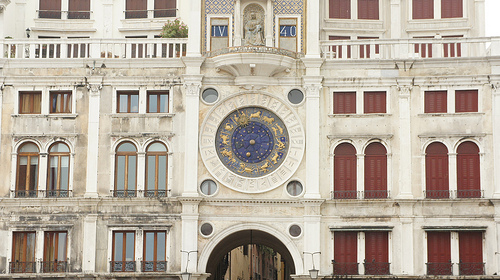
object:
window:
[421, 91, 442, 113]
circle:
[200, 86, 219, 103]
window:
[333, 142, 362, 198]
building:
[0, 7, 490, 279]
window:
[46, 140, 71, 196]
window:
[116, 91, 138, 112]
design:
[231, 121, 275, 163]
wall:
[394, 91, 422, 219]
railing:
[21, 230, 26, 269]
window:
[456, 90, 476, 111]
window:
[458, 230, 484, 275]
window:
[334, 230, 358, 272]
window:
[144, 231, 166, 268]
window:
[115, 230, 132, 267]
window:
[13, 230, 36, 270]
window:
[149, 93, 168, 112]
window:
[45, 92, 73, 115]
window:
[147, 137, 168, 193]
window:
[113, 138, 137, 192]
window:
[15, 141, 40, 195]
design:
[84, 59, 109, 76]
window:
[141, 140, 170, 198]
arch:
[197, 223, 303, 275]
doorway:
[202, 232, 296, 279]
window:
[41, 229, 70, 273]